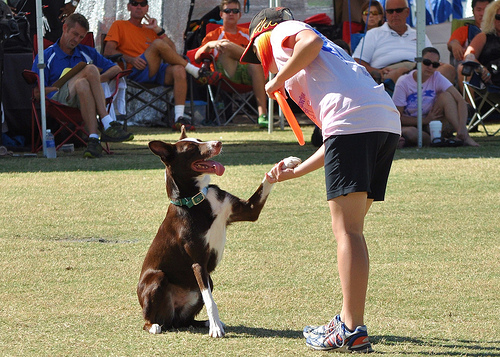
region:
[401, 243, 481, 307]
part of some grass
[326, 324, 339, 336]
part of some shoe laces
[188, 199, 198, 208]
part of a belt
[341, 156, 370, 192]
part of a black pant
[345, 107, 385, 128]
part of a white top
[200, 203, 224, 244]
chest of a dog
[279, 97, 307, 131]
part of an orange dish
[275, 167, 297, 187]
right hand of a lady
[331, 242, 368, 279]
left leg of the lady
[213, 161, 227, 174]
tongue of a dog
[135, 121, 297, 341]
a dog putting its paw in a girl's hand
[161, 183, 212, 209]
a green dog collar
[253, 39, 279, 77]
hair dyed orange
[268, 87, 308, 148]
an orange frisbee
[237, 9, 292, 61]
a black cap with a red bill and flames on the left side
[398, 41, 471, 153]
a woman wearing dark sunglasses sitting on the ground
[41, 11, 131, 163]
a man in a blue shirt sitting in a chair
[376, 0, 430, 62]
a man wearing dark sunglasses and a white shirt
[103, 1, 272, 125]
two men wearing dark sunglasses and wearing orange shirts sitting in chairs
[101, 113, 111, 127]
a white sock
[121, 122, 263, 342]
dog sitting on grass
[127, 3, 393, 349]
dog shaking hands with a person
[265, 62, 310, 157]
person holding an orange Frisbee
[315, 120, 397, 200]
person wearing black shorts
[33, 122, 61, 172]
water bottle on the ground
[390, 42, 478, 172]
person sitting on the ground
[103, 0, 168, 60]
person wearing an orange shirt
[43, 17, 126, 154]
man sitting with his legs crossed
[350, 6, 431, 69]
person wearing a white shirt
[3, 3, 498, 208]
spectators looking towards dog and person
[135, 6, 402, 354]
Woman holding a brown and white dog's paw.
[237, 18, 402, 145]
Woman holding an orange Frisbee.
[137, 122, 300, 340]
Brown and white dog sitting on the ground.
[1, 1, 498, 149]
Men and women watching the woman and dog.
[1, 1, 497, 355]
Men and women at a dog show.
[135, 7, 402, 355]
Brown and white dog performing at a show.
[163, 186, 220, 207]
Green collar on the dog's neck.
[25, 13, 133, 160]
Man in blue shirt sitting on a red chair.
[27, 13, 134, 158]
Man sitting in a red chair holding a brown clipboard.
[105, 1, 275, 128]
Men wearing sunglasses and orange t-shirts.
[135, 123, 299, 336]
brown and white dog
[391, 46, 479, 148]
woman sitting on the ground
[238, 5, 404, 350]
person shaking the dog's hand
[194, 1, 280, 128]
person in orange shirt and green tennis shoes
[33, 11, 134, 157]
person using a clipboard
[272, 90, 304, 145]
orange frisbee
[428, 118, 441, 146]
white cup on the grass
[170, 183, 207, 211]
green collar on the dog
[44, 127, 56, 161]
water bottle with blue label on the grass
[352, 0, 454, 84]
man in white shirt and sunglasses